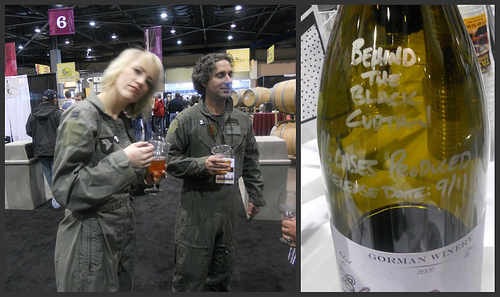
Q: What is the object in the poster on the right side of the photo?
A: Wine bottle.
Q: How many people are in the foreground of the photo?
A: Two.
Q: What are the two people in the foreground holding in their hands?
A: Glasses.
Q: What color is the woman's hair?
A: Blonde.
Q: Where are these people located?
A: Convention room.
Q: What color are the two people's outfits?
A: Olive.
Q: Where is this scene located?
A: At a convention.